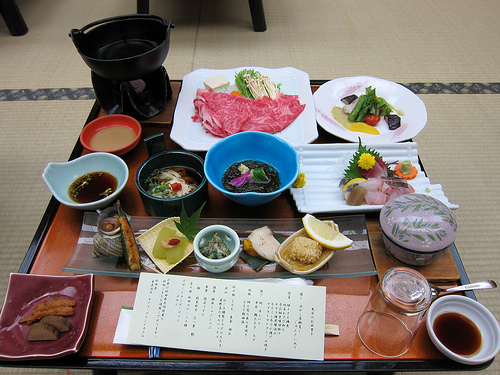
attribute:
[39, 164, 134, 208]
sauce — soy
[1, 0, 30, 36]
leg — black 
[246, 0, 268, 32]
leg — black 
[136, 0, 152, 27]
leg — black 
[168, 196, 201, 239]
leaf — decorative, green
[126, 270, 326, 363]
receipt — white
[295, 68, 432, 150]
plate — white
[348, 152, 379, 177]
flower — Small , yellow, decoration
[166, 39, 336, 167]
plate — square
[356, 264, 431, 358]
tglass — clear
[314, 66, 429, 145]
plate — purple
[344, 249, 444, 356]
glass — over turned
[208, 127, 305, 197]
bowl — blue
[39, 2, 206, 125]
cooking device — small, black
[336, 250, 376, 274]
glass dish — glass 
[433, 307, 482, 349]
liquid — brown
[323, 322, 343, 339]
chopsticks — pair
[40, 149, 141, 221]
bowl — orange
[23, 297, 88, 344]
meat — pink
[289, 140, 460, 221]
plate — ridged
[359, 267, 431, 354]
glass — small, upside down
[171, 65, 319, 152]
plate — white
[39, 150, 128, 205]
bowl — small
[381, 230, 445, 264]
dish — designed, ceramic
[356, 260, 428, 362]
glass — clear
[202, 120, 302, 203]
bowl — blue